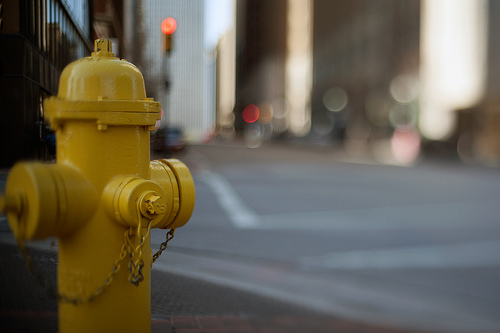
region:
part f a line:
[423, 233, 450, 259]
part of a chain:
[136, 210, 173, 302]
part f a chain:
[115, 277, 149, 312]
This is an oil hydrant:
[9, 27, 215, 327]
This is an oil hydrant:
[10, 22, 232, 329]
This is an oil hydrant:
[7, 30, 205, 330]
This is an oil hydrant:
[12, 27, 222, 329]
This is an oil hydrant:
[10, 24, 191, 326]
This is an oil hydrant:
[0, 28, 205, 328]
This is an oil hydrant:
[13, 30, 202, 330]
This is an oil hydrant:
[23, 10, 218, 327]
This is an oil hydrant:
[1, 18, 215, 331]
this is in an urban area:
[23, 21, 433, 311]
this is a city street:
[40, 21, 459, 282]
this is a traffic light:
[152, 14, 200, 56]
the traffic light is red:
[149, 8, 194, 52]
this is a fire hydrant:
[20, 54, 233, 279]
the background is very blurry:
[199, 86, 479, 281]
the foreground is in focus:
[37, 40, 230, 248]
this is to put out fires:
[47, 54, 222, 235]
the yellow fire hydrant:
[1, 37, 195, 330]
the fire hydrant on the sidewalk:
[0, 36, 196, 330]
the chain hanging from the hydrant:
[12, 216, 173, 303]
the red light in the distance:
[161, 18, 176, 31]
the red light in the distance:
[241, 103, 258, 123]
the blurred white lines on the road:
[190, 162, 499, 274]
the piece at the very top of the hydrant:
[93, 36, 111, 52]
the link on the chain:
[165, 230, 173, 240]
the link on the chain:
[159, 241, 167, 250]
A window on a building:
[46, 0, 53, 52]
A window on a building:
[76, 35, 79, 56]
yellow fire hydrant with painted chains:
[1, 27, 198, 331]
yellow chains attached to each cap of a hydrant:
[10, 197, 180, 309]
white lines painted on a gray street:
[182, 141, 499, 274]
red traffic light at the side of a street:
[158, 16, 178, 56]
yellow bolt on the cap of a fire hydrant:
[144, 194, 169, 215]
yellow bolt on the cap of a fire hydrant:
[3, 189, 24, 217]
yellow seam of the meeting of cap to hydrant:
[40, 95, 162, 131]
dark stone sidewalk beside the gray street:
[3, 244, 358, 331]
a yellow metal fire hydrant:
[7, 38, 197, 332]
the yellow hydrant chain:
[57, 225, 172, 304]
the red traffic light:
[162, 19, 175, 31]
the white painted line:
[187, 144, 257, 230]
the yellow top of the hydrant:
[93, 37, 113, 52]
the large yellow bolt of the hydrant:
[138, 190, 165, 217]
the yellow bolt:
[0, 192, 23, 214]